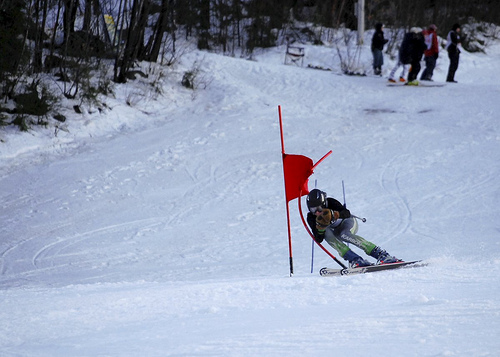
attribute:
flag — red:
[281, 153, 312, 204]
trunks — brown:
[49, 2, 149, 87]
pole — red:
[266, 85, 333, 277]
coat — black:
[302, 197, 349, 234]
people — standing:
[367, 16, 482, 98]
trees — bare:
[90, 11, 184, 86]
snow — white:
[113, 240, 215, 315]